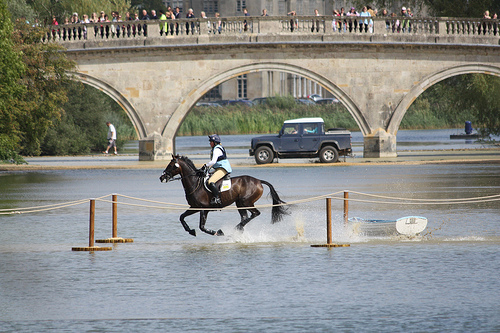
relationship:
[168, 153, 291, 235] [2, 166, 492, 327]
horse in water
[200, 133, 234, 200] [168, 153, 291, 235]
man on a horse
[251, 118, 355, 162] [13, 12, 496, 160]
truck under bridge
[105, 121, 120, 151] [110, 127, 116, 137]
man wearing a shirt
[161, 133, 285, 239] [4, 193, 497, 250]
horse and rider or on a rope course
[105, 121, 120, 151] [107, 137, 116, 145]
man wearing shorts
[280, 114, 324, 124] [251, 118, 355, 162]
top of a truck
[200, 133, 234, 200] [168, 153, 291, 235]
man on horse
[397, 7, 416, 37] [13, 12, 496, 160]
person on bridge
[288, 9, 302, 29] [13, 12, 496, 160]
person on bridge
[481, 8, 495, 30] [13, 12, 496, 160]
person on bridge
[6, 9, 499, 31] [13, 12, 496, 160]
people on bridge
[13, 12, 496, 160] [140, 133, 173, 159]
bridge of stone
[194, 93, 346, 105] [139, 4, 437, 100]
cars in front of building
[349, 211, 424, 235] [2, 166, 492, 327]
boat on water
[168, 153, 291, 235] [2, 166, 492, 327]
horse crossing water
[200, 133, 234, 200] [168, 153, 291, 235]
person on horse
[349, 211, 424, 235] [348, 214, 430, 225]
boat with blue trim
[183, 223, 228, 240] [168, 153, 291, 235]
front feet of horse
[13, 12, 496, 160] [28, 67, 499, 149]
bridge has arches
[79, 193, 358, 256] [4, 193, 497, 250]
poles holding rope course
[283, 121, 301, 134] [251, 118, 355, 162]
window on a truck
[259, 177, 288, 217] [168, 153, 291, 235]
tail of a horse